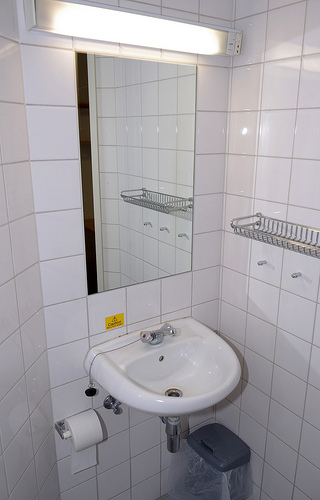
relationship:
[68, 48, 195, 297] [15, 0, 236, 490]
mirror attached to wall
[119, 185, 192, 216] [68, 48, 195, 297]
reflection seen in mirror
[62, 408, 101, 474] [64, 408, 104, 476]
roll of toilet paper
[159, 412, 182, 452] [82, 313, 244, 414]
pipe under sink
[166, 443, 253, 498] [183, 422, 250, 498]
bag in trash can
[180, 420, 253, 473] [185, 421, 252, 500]
lid on can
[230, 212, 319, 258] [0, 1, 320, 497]
shelf on wall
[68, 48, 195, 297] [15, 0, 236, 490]
mirror on wall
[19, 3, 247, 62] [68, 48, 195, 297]
light at top of mirror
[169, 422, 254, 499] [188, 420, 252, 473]
garbage in can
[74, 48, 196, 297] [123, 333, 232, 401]
mirror hanging over sink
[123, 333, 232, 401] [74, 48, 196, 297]
sink below mirror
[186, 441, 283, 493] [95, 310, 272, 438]
can under sink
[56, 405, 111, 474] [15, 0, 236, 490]
toilet paper on wall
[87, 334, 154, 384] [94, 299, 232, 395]
chain on sink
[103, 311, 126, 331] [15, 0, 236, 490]
sign on wall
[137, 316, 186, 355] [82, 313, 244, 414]
faucet on sink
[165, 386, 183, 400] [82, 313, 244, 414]
drain in sink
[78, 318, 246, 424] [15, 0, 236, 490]
sink on wall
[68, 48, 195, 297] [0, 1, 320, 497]
mirror on wall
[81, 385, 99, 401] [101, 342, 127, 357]
plug on chain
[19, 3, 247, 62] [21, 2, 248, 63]
light in holder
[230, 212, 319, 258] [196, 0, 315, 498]
shelf on wall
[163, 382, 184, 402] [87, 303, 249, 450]
drain on sink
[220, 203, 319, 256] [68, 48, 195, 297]
shelf on mirror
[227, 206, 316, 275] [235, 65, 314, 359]
rack on wall